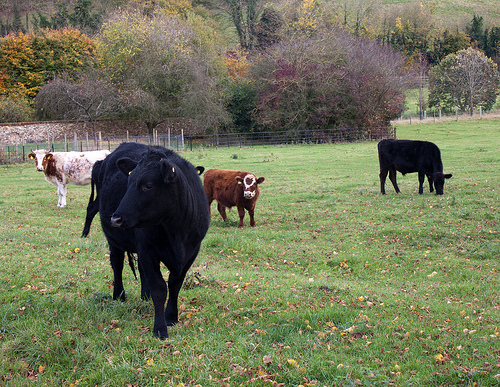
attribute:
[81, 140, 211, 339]
cow — large, black, furry, white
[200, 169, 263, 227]
cow — brown, white, small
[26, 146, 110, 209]
cow — brown, white, spotted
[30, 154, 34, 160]
tag — yellow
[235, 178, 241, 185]
tag — plastic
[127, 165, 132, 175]
tag — yellow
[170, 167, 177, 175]
tag — plastic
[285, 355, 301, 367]
leaf — dry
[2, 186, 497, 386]
leaves — dry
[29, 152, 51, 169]
face — white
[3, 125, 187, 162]
fence — wooden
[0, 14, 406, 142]
trees — colorful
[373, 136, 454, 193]
cow — black, grazing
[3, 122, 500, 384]
grass — green